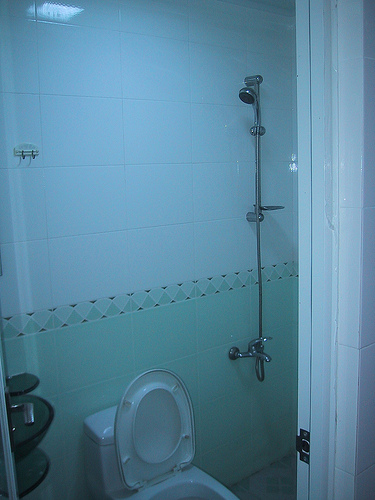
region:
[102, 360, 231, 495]
white toilet with seat up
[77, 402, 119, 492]
toilet tank in front of wall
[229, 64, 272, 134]
shower head next to wall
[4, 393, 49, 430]
knob on bathroom door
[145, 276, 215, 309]
border design on tile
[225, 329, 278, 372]
faucet on bathroom wall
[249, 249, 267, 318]
hose attached to shower head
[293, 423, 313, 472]
metal plate on door frame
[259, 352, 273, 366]
light reflection on faucet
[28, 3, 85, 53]
light reflection on white tile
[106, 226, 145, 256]
Shower tile in bathroom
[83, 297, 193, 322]
Decrative tile in a bathroom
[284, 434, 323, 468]
Door lock in bathroom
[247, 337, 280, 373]
Shower faucet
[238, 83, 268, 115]
Shower head in the shower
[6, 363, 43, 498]
Product holder in the bathroom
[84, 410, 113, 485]
Toilet tank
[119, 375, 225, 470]
Toilet seat in the bathroom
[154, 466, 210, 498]
Toilet in the bathroom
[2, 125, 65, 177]
Clothes hook in the bathroom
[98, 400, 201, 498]
this is a toilet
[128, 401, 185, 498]
the toilet is white in color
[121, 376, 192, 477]
this is a toilet seat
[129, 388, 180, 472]
the toilet seat is white in color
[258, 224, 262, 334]
this is a pipe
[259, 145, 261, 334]
the pipe is metallic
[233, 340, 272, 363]
this is a tap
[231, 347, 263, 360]
the tap is metallic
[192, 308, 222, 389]
this is the wall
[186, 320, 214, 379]
the wall is white in color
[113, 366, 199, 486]
white plastic toilet lid up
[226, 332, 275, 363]
metal faucet with handle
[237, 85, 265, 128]
metal and plastic shower head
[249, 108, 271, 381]
long metallic shower hose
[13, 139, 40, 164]
plastic and metal hanger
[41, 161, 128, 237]
large white square tile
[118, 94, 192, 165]
large white square tile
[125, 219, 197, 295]
large white square tile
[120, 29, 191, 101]
large white square tile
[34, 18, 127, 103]
large white square tile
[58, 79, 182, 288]
this is a wall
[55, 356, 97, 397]
the wall is white in color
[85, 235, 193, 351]
the wall is made of tiles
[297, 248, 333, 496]
this is the door frame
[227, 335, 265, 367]
the tap is metallic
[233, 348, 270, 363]
the tap is shiny